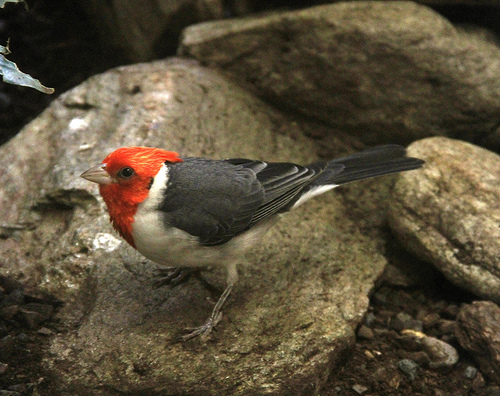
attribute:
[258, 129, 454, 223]
tail — black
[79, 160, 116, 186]
beak — short